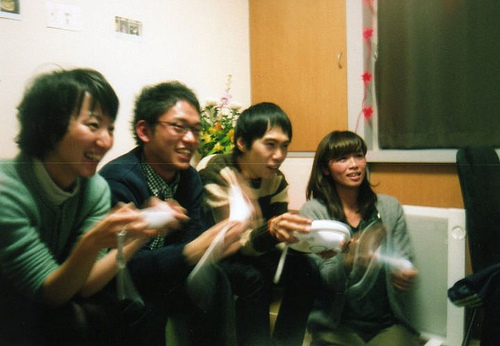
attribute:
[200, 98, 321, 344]
man — playing games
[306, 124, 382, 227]
hair — long, dark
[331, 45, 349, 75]
door handle — metal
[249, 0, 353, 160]
door — wooden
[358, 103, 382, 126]
star — red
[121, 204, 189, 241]
remote — white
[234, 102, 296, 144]
hair — dark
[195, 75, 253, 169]
flowers — potted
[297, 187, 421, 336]
sweater — gray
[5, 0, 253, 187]
wall — white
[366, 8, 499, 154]
curtains — green